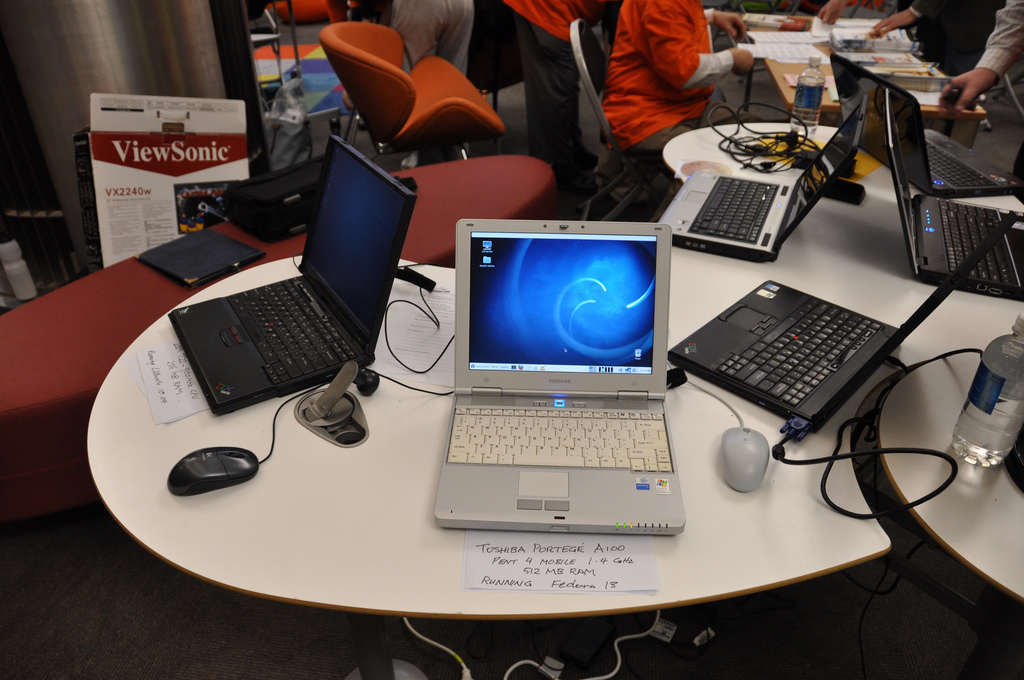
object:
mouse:
[722, 427, 769, 492]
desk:
[83, 120, 1024, 620]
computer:
[430, 217, 684, 537]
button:
[605, 438, 621, 448]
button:
[559, 438, 573, 450]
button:
[469, 434, 485, 446]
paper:
[463, 529, 660, 595]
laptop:
[165, 137, 419, 418]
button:
[616, 423, 644, 471]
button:
[268, 332, 285, 346]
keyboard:
[167, 276, 372, 415]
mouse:
[165, 447, 258, 497]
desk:
[258, 506, 367, 575]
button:
[452, 408, 498, 444]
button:
[573, 420, 672, 529]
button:
[551, 448, 567, 457]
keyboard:
[447, 408, 671, 472]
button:
[600, 456, 616, 468]